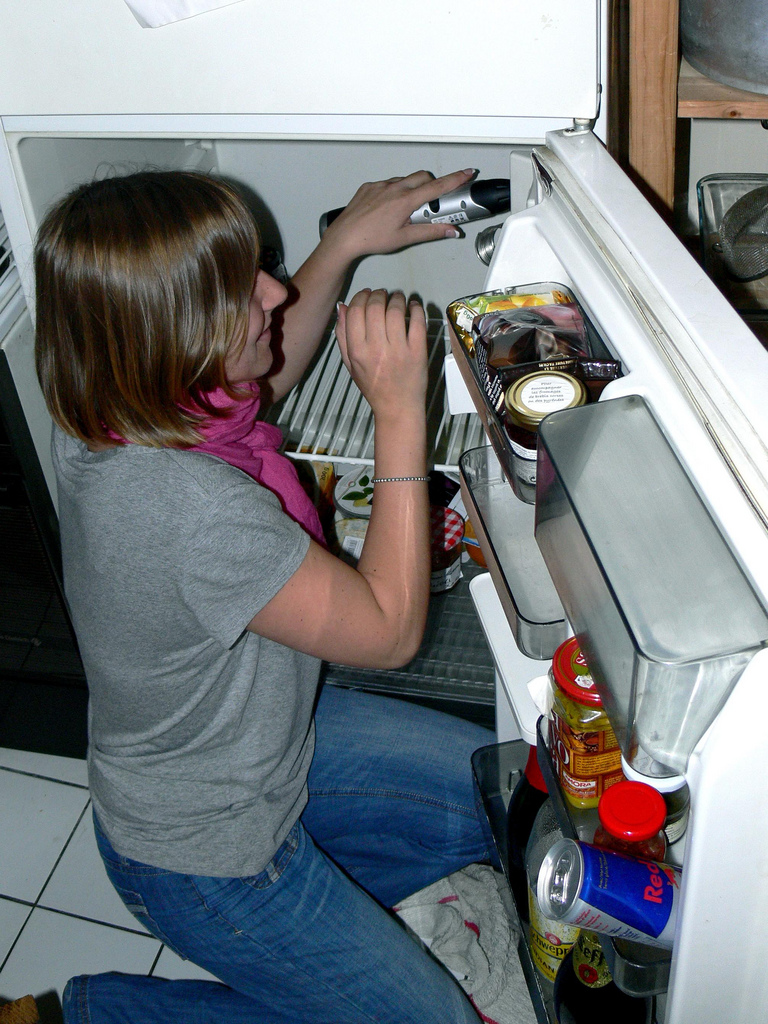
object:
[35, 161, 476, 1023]
woman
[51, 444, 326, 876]
shirt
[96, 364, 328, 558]
scarf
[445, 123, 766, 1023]
door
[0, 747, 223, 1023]
ground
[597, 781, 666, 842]
lid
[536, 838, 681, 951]
bottle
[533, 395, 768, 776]
shelf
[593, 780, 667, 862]
bottle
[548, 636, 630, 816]
bottle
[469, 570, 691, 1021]
shelf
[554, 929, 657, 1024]
bottle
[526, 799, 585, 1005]
bottle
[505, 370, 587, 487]
bottle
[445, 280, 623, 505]
shelf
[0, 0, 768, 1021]
fridge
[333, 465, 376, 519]
bottle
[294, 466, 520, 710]
shelf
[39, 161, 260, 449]
hair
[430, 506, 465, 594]
food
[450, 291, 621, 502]
food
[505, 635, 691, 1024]
food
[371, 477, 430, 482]
bracelet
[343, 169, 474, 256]
hand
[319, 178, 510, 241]
screwdriver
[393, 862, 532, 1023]
towel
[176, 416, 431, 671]
arm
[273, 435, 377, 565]
food